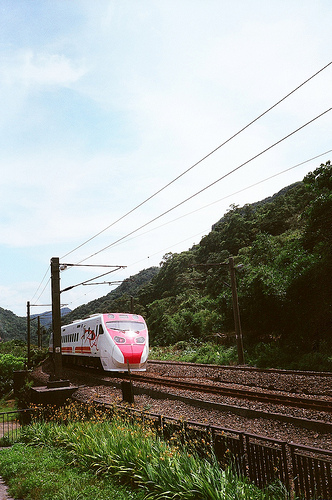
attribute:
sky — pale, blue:
[4, 7, 302, 143]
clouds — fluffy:
[17, 43, 98, 95]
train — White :
[65, 317, 146, 364]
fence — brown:
[1, 397, 329, 499]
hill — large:
[167, 174, 325, 372]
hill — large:
[42, 271, 192, 360]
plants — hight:
[22, 391, 330, 498]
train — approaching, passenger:
[61, 308, 151, 376]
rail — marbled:
[212, 75, 327, 176]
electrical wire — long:
[19, 52, 330, 307]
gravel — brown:
[29, 360, 331, 499]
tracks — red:
[80, 305, 154, 376]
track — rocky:
[240, 385, 310, 441]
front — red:
[100, 310, 151, 373]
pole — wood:
[49, 256, 65, 379]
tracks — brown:
[110, 369, 330, 431]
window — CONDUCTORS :
[105, 321, 144, 331]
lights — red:
[117, 336, 143, 344]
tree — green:
[235, 240, 316, 346]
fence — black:
[72, 397, 321, 492]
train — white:
[45, 311, 150, 371]